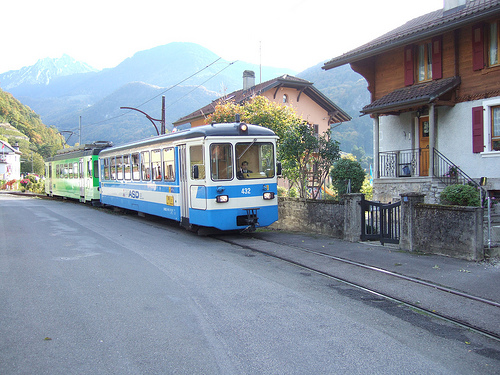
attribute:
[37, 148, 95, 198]
train — green, white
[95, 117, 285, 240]
train — blue, white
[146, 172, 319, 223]
light — white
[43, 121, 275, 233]
train — green, white, blue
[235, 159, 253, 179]
person — sitting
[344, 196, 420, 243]
gate — black